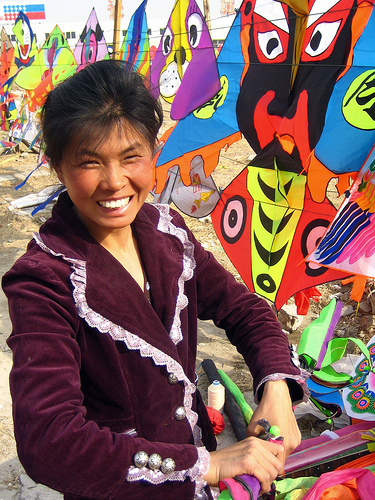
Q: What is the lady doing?
A: Smiling.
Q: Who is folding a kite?
A: A woman.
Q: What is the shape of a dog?
A: Kite.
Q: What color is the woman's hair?
A: Black.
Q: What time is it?
A: Afternoon.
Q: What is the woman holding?
A: A kite.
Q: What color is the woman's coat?
A: Maroon.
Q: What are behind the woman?
A: Different types of kites.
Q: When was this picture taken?
A: During the daytime.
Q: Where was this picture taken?
A: Taken outside.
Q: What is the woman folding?
A: A kite.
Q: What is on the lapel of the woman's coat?
A: White lace.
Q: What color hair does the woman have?
A: Black.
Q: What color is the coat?
A: Purple.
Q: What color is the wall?
A: Multi colors.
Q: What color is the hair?
A: Black.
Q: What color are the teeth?
A: White.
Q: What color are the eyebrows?
A: Black.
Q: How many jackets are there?
A: One.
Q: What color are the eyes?
A: Black.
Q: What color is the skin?
A: Peach.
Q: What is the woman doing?
A: Smiling.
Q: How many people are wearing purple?
A: One.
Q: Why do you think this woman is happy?
A: She is smiling.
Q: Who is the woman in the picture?
A: An oriental woman.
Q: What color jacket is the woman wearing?
A: Wine.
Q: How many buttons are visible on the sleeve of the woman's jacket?
A: Three.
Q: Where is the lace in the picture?
A: On the woman's jacket.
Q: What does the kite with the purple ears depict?
A: A dog.